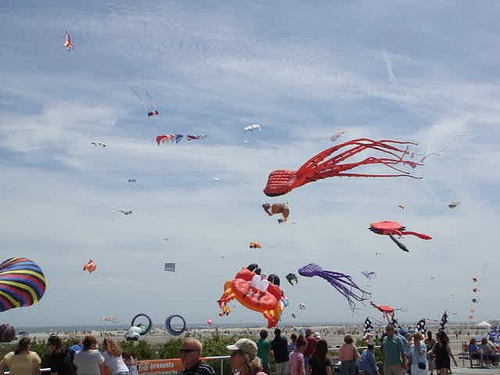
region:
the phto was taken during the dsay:
[4, 35, 488, 365]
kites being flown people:
[236, 203, 422, 320]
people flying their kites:
[263, 334, 360, 372]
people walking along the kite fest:
[173, 339, 258, 363]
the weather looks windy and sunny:
[36, 101, 386, 258]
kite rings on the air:
[115, 317, 187, 340]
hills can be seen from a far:
[51, 319, 128, 336]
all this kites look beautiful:
[61, 202, 442, 364]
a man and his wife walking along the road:
[385, 324, 430, 371]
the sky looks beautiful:
[2, 88, 121, 246]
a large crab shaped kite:
[215, 256, 291, 330]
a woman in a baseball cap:
[220, 335, 271, 372]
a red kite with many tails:
[262, 130, 434, 205]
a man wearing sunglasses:
[172, 337, 214, 372]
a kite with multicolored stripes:
[0, 255, 51, 317]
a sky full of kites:
[2, 1, 497, 326]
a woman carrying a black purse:
[405, 330, 432, 372]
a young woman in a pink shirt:
[285, 330, 307, 373]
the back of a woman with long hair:
[97, 332, 128, 372]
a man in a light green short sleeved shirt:
[376, 322, 409, 374]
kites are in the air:
[240, 148, 462, 324]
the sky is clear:
[11, 2, 491, 237]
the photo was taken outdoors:
[15, 160, 480, 350]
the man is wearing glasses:
[172, 332, 207, 367]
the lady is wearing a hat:
[220, 335, 255, 370]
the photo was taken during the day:
[6, 24, 498, 374]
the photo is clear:
[4, 33, 494, 366]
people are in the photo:
[6, 321, 468, 373]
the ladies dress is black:
[428, 327, 460, 373]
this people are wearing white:
[73, 345, 134, 374]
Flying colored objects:
[217, 114, 424, 322]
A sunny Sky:
[0, 0, 115, 150]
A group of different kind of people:
[15, 326, 397, 372]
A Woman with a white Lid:
[226, 335, 263, 361]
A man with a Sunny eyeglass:
[169, 331, 205, 373]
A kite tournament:
[1, 153, 494, 370]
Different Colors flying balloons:
[448, 258, 495, 370]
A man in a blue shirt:
[378, 328, 410, 373]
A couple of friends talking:
[461, 306, 494, 371]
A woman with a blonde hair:
[98, 333, 142, 372]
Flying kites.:
[261, 151, 403, 325]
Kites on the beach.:
[36, 157, 357, 363]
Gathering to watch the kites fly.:
[168, 107, 457, 372]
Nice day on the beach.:
[10, 206, 301, 369]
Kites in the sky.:
[96, 80, 253, 222]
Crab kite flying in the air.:
[202, 237, 300, 330]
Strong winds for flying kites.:
[18, 105, 457, 360]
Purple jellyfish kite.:
[293, 238, 380, 310]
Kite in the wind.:
[331, 152, 461, 293]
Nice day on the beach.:
[62, 120, 397, 343]